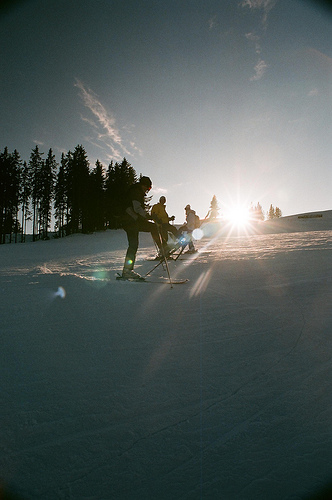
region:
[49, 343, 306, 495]
snow is white and powdery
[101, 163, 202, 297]
person wearing snow skis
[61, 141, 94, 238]
Large green evergreen tree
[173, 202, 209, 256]
Person wearing white jacket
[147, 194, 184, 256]
Person wearing yellow jacket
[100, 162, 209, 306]
Group of people on skis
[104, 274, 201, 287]
Long wooden snow ski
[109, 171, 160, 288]
Person wearing goggles and skis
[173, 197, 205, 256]
Person wearing white coat and hat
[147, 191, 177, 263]
Person holding ski poles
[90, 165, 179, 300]
Person standing on one foot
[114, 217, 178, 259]
the skier has his leg raised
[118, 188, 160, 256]
the skier is wearing a dark outfit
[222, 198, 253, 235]
the sun is in the horizon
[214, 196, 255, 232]
the sun is going down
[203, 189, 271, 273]
the sun is emitting rays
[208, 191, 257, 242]
the sun is white in color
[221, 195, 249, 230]
the sun is extremely bright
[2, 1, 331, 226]
the sky is getting dark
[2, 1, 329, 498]
the photo was taken outdoors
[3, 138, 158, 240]
pine trees are in the background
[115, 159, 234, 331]
people skiing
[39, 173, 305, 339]
three skiers on a hill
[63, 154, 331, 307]
three people on skis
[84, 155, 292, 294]
three people ski while the sun sets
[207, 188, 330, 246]
the sun is setting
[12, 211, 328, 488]
a snowy landscape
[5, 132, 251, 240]
pine trees are beside the hill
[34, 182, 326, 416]
the hill is covered with snow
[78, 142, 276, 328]
the skiers are talking to each other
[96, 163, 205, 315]
one skier has a ski lifted off the ground